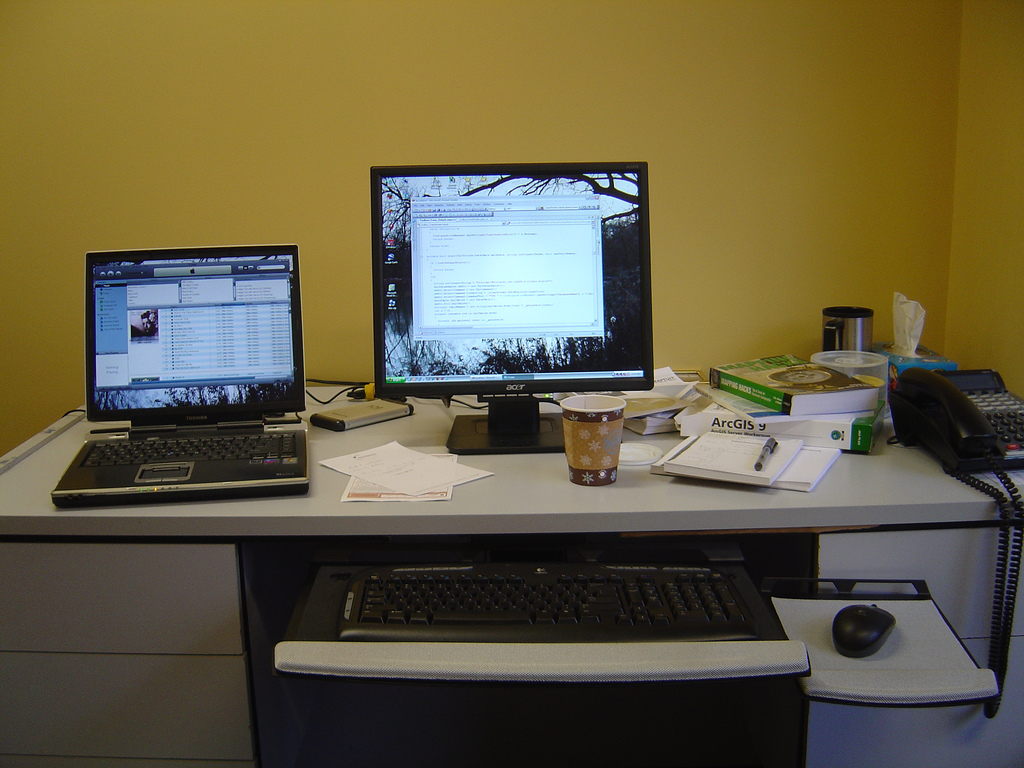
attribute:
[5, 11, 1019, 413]
walls — dark yellow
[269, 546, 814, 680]
keyboard — black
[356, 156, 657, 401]
screen — large, square, black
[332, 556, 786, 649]
keyboard — large, wide, long